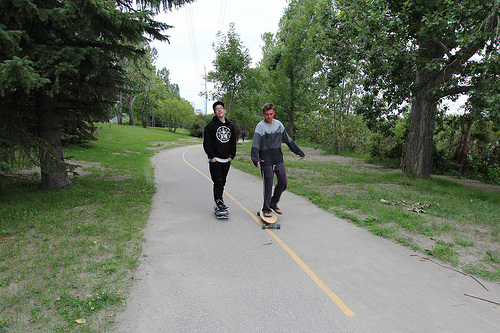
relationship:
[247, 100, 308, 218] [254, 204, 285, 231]
guy using skateboard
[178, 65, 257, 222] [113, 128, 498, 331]
guy skateboarding on path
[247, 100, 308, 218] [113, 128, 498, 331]
guy skateboarding on path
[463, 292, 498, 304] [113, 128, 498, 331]
stick on path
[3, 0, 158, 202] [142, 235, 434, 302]
tree on side of road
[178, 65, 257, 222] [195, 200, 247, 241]
guy using skateboard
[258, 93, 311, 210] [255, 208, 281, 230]
boy on skateboard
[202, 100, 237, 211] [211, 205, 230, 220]
boy on skateboard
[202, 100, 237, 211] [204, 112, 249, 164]
boy wearing sweatshirt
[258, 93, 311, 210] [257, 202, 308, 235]
boy on skateboard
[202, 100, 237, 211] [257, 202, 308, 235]
boy on skateboard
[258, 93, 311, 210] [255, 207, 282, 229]
boy on a skateboard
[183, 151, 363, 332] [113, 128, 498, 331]
yellow line down middle of path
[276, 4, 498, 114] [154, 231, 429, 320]
tall trees on side of road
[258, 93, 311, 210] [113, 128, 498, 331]
boy skateboarding on path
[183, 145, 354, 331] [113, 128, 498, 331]
line on path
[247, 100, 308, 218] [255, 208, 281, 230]
guy on skateboard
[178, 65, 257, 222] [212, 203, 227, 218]
guy on skateboard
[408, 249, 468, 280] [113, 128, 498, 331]
limbs on path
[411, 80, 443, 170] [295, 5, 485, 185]
trunk of tree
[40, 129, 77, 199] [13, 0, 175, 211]
trunk of tree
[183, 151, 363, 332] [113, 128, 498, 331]
yellow line on path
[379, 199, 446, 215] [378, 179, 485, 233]
wood in grass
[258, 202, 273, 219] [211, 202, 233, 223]
feet on skateboard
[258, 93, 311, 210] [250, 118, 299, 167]
boy wearing sweater